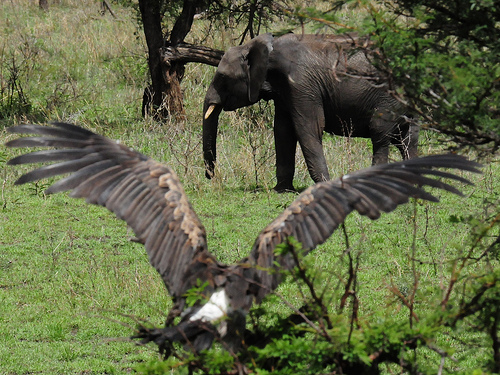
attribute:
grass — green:
[3, 0, 498, 374]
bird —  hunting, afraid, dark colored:
[13, 131, 472, 357]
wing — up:
[250, 152, 483, 296]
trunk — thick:
[190, 90, 227, 194]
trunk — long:
[186, 85, 228, 172]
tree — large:
[131, 6, 203, 118]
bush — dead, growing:
[162, 91, 204, 190]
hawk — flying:
[1, 116, 486, 363]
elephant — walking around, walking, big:
[202, 31, 419, 191]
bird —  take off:
[8, 112, 478, 374]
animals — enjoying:
[18, 17, 497, 328]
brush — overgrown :
[322, 267, 477, 353]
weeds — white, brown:
[0, 0, 494, 375]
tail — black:
[126, 318, 224, 363]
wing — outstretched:
[212, 159, 417, 252]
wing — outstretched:
[62, 127, 193, 278]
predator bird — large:
[6, 115, 490, 335]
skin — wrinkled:
[311, 67, 348, 103]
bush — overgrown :
[301, 0, 499, 162]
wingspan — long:
[1, 90, 492, 291]